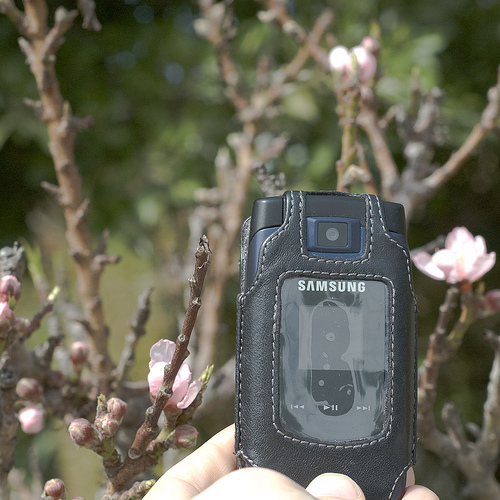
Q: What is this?
A: Cellphone.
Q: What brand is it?
A: Samsung.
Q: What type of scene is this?
A: Outdoor.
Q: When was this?
A: Daytime.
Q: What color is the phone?
A: Black.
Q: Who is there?
A: A person.